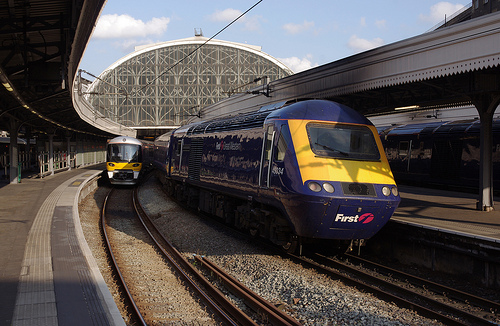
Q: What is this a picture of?
A: Trains.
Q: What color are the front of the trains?
A: Yellow.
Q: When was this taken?
A: Daytime.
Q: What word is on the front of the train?
A: First.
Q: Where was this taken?
A: Train station.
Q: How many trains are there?
A: 2.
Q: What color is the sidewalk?
A: Gray.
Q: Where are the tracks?
A: Under the train.